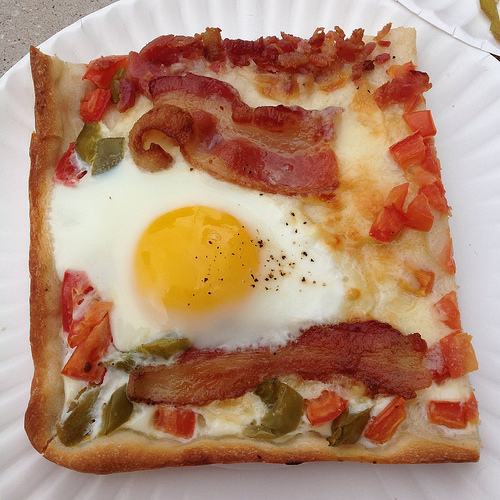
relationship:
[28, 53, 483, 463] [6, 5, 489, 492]
pizza on dish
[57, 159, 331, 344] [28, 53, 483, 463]
egg on pizza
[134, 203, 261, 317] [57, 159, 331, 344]
yolk from egg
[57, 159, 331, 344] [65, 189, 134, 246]
egg has white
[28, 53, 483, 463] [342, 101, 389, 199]
pizza has cheese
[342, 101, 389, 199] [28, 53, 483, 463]
cheese on pizza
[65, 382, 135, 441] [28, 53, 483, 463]
pepper on pizza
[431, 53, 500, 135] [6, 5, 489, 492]
white colored dish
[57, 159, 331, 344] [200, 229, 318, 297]
egg has pepper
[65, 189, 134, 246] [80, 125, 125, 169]
egg white has jalapeno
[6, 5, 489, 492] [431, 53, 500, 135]
paper made of paper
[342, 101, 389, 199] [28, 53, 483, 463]
cheese on bread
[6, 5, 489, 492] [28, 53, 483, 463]
plate has food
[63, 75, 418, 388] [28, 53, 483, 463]
breakfast on square cut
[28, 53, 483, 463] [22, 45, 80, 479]
breakfast pizza has brown crust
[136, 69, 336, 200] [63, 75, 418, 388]
bacon on top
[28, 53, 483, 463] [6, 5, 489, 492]
pizza on plate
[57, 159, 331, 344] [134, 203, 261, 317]
egg has yellow yolk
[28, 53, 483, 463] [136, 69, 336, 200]
pizza has strip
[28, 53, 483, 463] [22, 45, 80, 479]
pizza has brown crust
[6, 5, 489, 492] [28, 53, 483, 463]
paper plate has breakfast pizza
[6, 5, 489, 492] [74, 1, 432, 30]
plate has fluted edges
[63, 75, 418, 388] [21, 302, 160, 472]
breakfast meal slice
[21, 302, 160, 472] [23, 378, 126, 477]
slice has a corner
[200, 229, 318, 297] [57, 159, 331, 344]
sprinkled pepper on egg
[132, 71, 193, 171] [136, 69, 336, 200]
curled fat on bacon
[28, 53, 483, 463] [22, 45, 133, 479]
breakfast pizza has brown crust